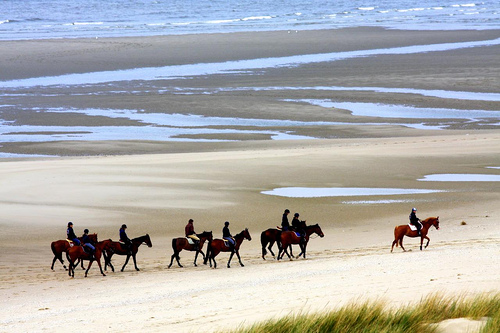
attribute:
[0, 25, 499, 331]
sand — brown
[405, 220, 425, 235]
covering — white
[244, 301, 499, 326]
grass — tall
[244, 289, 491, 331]
grass — along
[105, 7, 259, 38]
water — blue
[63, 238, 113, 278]
fur — brown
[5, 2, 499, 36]
ocean — background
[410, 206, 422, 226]
rider — lead, horse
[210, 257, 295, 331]
sand — bad sentence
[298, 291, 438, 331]
grass — green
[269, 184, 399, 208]
water — along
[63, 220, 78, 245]
person — riding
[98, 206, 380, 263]
horses — brown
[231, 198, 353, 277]
horses — some